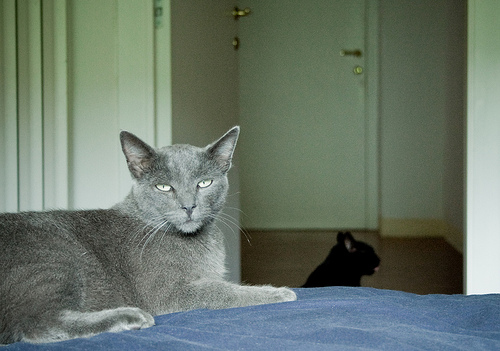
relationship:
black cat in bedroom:
[301, 229, 383, 288] [12, 5, 494, 345]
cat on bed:
[0, 124, 297, 344] [216, 189, 497, 326]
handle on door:
[339, 49, 361, 58] [237, 0, 378, 228]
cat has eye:
[5, 122, 298, 338] [154, 183, 171, 190]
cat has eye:
[5, 122, 298, 338] [199, 177, 214, 185]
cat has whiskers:
[5, 122, 298, 338] [120, 203, 254, 262]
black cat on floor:
[301, 229, 383, 288] [238, 225, 467, 299]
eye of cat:
[155, 183, 175, 190] [5, 122, 298, 338]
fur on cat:
[25, 252, 160, 300] [49, 145, 242, 249]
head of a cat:
[132, 142, 229, 234] [5, 122, 298, 338]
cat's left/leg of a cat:
[12, 301, 162, 346] [5, 122, 298, 338]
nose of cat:
[174, 192, 206, 210] [5, 122, 298, 338]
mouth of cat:
[164, 208, 210, 230] [9, 133, 273, 313]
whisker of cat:
[120, 212, 172, 261] [95, 139, 285, 290]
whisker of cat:
[132, 209, 172, 251] [5, 122, 298, 338]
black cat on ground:
[301, 229, 383, 288] [238, 224, 468, 294]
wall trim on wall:
[383, 219, 454, 237] [387, 2, 461, 236]